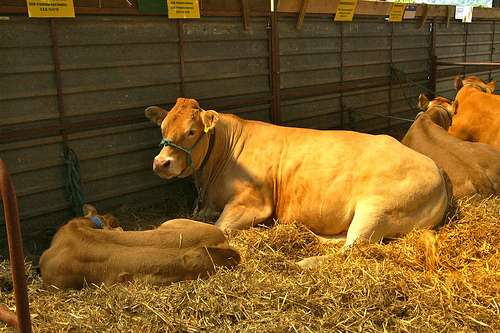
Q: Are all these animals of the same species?
A: Yes, all the animals are cows.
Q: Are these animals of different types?
A: No, all the animals are cows.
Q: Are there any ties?
A: Yes, there is a tie.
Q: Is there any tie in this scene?
A: Yes, there is a tie.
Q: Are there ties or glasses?
A: Yes, there is a tie.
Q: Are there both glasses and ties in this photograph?
A: No, there is a tie but no glasses.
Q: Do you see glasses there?
A: No, there are no glasses.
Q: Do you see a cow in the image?
A: Yes, there is a cow.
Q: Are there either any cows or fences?
A: Yes, there is a cow.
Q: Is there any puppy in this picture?
A: No, there are no puppies.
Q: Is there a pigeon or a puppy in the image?
A: No, there are no puppies or pigeons.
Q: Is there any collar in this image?
A: Yes, there is a collar.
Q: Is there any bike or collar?
A: Yes, there is a collar.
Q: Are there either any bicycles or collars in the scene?
A: Yes, there is a collar.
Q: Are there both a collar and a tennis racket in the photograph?
A: No, there is a collar but no rackets.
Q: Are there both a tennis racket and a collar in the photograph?
A: No, there is a collar but no rackets.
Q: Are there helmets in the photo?
A: No, there are no helmets.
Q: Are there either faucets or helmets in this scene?
A: No, there are no helmets or faucets.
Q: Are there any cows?
A: Yes, there is a cow.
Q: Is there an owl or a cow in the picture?
A: Yes, there is a cow.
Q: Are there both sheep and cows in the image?
A: No, there is a cow but no sheep.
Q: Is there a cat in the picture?
A: No, there are no cats.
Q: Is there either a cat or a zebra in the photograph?
A: No, there are no cats or zebras.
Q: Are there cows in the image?
A: Yes, there is a cow.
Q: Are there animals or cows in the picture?
A: Yes, there is a cow.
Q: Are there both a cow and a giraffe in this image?
A: No, there is a cow but no giraffes.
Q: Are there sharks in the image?
A: No, there are no sharks.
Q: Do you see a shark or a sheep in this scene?
A: No, there are no sharks or sheep.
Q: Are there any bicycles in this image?
A: No, there are no bicycles.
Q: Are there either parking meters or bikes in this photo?
A: No, there are no bikes or parking meters.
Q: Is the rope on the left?
A: Yes, the rope is on the left of the image.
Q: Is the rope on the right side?
A: No, the rope is on the left of the image.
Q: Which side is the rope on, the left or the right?
A: The rope is on the left of the image.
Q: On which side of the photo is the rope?
A: The rope is on the left of the image.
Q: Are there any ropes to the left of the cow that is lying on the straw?
A: Yes, there is a rope to the left of the cow.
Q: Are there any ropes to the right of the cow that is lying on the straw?
A: No, the rope is to the left of the cow.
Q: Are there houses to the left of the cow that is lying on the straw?
A: No, there is a rope to the left of the cow.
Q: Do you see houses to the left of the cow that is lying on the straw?
A: No, there is a rope to the left of the cow.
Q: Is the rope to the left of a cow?
A: Yes, the rope is to the left of a cow.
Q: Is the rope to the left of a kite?
A: No, the rope is to the left of a cow.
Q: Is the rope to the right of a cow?
A: No, the rope is to the left of a cow.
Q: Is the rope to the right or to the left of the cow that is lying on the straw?
A: The rope is to the left of the cow.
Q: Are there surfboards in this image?
A: No, there are no surfboards.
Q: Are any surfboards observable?
A: No, there are no surfboards.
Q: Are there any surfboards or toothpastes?
A: No, there are no surfboards or toothpastes.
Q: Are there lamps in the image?
A: No, there are no lamps.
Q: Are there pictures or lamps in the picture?
A: No, there are no lamps or pictures.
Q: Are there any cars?
A: No, there are no cars.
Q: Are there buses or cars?
A: No, there are no cars or buses.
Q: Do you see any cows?
A: Yes, there is a cow.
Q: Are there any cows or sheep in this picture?
A: Yes, there is a cow.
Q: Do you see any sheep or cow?
A: Yes, there is a cow.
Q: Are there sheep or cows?
A: Yes, there is a cow.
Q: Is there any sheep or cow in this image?
A: Yes, there is a cow.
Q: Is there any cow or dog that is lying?
A: Yes, the cow is lying.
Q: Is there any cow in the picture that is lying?
A: Yes, there is a cow that is lying.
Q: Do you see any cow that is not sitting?
A: Yes, there is a cow that is lying .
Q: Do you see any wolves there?
A: No, there are no wolves.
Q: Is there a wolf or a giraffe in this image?
A: No, there are no wolves or giraffes.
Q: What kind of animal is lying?
A: The animal is a cow.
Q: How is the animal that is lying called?
A: The animal is a cow.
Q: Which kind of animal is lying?
A: The animal is a cow.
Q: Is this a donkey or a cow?
A: This is a cow.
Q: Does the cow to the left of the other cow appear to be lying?
A: Yes, the cow is lying.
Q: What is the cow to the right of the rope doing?
A: The cow is lying.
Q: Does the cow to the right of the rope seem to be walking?
A: No, the cow is lying.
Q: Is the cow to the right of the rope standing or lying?
A: The cow is lying.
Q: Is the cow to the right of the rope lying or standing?
A: The cow is lying.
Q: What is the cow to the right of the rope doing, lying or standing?
A: The cow is lying.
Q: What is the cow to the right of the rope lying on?
A: The cow is lying on the straw.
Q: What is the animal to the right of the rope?
A: The animal is a cow.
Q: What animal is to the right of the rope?
A: The animal is a cow.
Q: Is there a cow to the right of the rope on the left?
A: Yes, there is a cow to the right of the rope.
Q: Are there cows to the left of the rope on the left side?
A: No, the cow is to the right of the rope.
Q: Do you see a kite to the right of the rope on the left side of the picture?
A: No, there is a cow to the right of the rope.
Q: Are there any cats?
A: No, there are no cats.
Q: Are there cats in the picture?
A: No, there are no cats.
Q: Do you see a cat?
A: No, there are no cats.